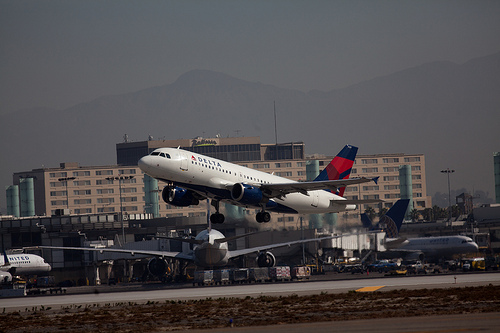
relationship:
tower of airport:
[167, 140, 307, 162] [1, 133, 498, 310]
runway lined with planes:
[2, 270, 498, 312] [359, 214, 489, 261]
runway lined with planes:
[2, 270, 498, 312] [21, 197, 388, 283]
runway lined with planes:
[2, 270, 498, 312] [1, 251, 51, 288]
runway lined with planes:
[2, 270, 498, 312] [136, 145, 385, 223]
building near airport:
[7, 128, 433, 234] [0, 207, 498, 286]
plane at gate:
[116, 136, 480, 263] [41, 190, 489, 297]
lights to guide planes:
[437, 160, 457, 203] [0, 135, 490, 300]